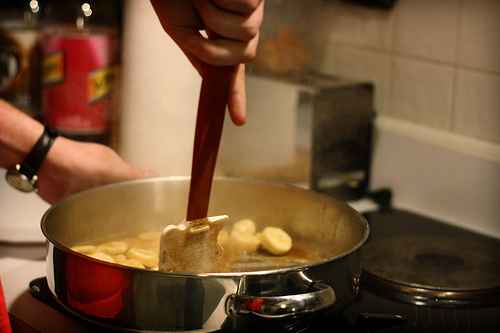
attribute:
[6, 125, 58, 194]
watch — black, leather, brown, round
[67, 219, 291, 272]
banana — sliced, large, cut, white, cooking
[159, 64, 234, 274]
spatula — rubber, broken, white, wooden, wood, resistant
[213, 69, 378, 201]
toaster — silver, shiny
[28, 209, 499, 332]
stove — silver, electical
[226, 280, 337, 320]
handle — silver, shiny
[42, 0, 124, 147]
bottle — pink, soda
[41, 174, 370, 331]
pan — round, silvery, steel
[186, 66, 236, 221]
handle — wooden, brown, red, plastic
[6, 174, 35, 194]
face — silver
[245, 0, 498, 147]
tile — white, back splash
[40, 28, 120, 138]
can — red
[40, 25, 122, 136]
label — red, yellow